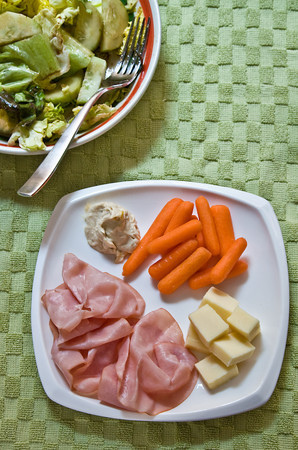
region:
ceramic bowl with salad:
[0, 0, 160, 155]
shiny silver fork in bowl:
[16, 13, 147, 196]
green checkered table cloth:
[0, 0, 295, 447]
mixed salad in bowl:
[0, 0, 144, 150]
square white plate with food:
[28, 177, 287, 418]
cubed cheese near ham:
[186, 300, 224, 339]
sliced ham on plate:
[40, 250, 195, 411]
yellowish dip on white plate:
[81, 196, 137, 259]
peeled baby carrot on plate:
[142, 216, 198, 249]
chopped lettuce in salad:
[1, 33, 59, 77]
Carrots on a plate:
[125, 191, 226, 297]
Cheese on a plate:
[179, 288, 265, 402]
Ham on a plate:
[35, 270, 146, 411]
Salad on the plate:
[2, 3, 115, 81]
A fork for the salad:
[57, 11, 151, 153]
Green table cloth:
[164, 67, 268, 140]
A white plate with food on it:
[33, 190, 267, 422]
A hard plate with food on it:
[13, 12, 159, 170]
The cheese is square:
[179, 294, 247, 414]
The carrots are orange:
[128, 189, 228, 297]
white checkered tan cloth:
[190, 65, 268, 125]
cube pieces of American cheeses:
[182, 304, 252, 379]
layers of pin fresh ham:
[61, 271, 162, 387]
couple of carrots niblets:
[156, 212, 233, 270]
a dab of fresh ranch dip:
[74, 215, 144, 245]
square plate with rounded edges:
[35, 175, 286, 425]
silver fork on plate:
[26, 3, 157, 200]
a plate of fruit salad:
[22, 5, 125, 101]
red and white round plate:
[0, 0, 146, 167]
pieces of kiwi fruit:
[82, 19, 130, 53]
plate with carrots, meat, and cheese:
[30, 178, 291, 421]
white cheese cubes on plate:
[184, 285, 261, 390]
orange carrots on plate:
[119, 193, 247, 296]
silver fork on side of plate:
[16, 15, 153, 200]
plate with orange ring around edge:
[0, 0, 161, 156]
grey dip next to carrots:
[83, 200, 141, 262]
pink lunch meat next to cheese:
[40, 251, 201, 418]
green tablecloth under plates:
[1, 0, 297, 448]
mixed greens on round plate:
[0, 0, 165, 158]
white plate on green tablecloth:
[30, 178, 290, 424]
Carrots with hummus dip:
[78, 189, 209, 273]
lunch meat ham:
[42, 272, 185, 414]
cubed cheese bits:
[181, 281, 270, 393]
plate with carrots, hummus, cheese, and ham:
[28, 186, 275, 418]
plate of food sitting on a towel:
[4, 174, 296, 436]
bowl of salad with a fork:
[0, 12, 186, 168]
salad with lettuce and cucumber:
[21, 6, 114, 82]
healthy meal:
[28, 6, 285, 438]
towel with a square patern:
[178, 15, 288, 153]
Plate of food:
[29, 191, 286, 417]